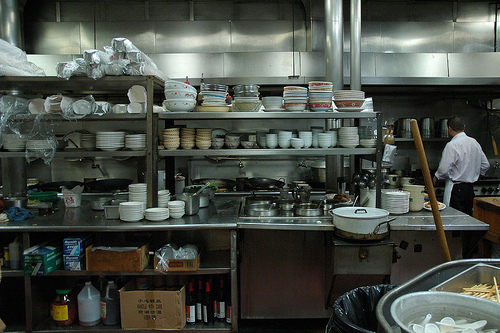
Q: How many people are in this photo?
A: One.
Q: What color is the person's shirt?
A: White.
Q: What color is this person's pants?
A: Black.